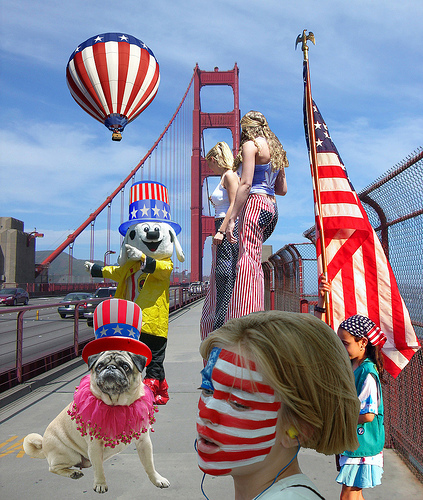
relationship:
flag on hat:
[306, 100, 420, 375] [114, 171, 194, 235]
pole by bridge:
[34, 65, 194, 277] [0, 61, 421, 498]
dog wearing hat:
[23, 350, 170, 495] [84, 296, 149, 366]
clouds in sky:
[300, 7, 420, 84] [7, 6, 57, 207]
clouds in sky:
[0, 0, 422, 282] [7, 6, 57, 207]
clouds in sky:
[0, 0, 422, 282] [336, 40, 395, 83]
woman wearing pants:
[223, 108, 289, 320] [223, 195, 275, 321]